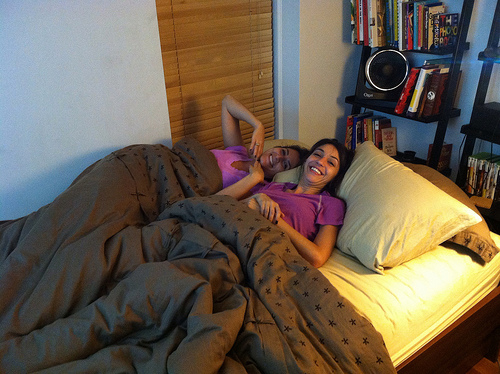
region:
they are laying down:
[255, 124, 365, 196]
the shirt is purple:
[301, 197, 326, 212]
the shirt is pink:
[220, 150, 230, 175]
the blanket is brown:
[161, 253, 197, 295]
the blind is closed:
[181, 66, 211, 98]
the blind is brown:
[236, 71, 261, 99]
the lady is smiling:
[308, 161, 325, 183]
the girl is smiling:
[263, 152, 278, 169]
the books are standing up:
[360, 8, 408, 36]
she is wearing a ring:
[253, 137, 262, 152]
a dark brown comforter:
[0, 139, 395, 372]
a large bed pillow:
[276, 141, 480, 271]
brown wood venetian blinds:
[155, 0, 275, 160]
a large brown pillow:
[403, 159, 498, 264]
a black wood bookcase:
[337, 0, 477, 169]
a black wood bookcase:
[448, 0, 499, 227]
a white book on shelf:
[407, 65, 443, 111]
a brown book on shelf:
[422, 69, 457, 117]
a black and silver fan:
[364, 48, 411, 98]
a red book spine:
[393, 69, 417, 116]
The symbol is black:
[269, 271, 286, 285]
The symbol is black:
[300, 285, 311, 300]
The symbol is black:
[309, 298, 324, 314]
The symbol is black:
[325, 313, 338, 333]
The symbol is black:
[336, 330, 351, 352]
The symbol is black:
[371, 350, 386, 366]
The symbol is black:
[356, 329, 373, 350]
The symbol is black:
[333, 294, 348, 318]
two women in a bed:
[183, 93, 368, 268]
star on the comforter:
[316, 303, 339, 335]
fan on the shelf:
[363, 47, 410, 97]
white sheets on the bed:
[387, 278, 430, 325]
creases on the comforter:
[110, 260, 166, 309]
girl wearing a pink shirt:
[210, 85, 301, 185]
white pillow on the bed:
[382, 177, 419, 237]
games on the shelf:
[460, 150, 498, 204]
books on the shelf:
[372, 20, 444, 47]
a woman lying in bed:
[246, 136, 344, 258]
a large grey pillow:
[313, 129, 473, 283]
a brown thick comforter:
[2, 144, 396, 372]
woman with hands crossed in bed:
[233, 132, 360, 266]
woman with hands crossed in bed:
[235, 125, 357, 261]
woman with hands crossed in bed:
[238, 129, 368, 266]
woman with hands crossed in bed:
[233, 128, 367, 268]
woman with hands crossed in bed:
[226, 135, 363, 276]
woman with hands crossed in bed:
[229, 126, 376, 271]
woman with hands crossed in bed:
[235, 128, 375, 268]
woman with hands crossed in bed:
[234, 128, 358, 268]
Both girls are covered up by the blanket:
[31, 83, 403, 372]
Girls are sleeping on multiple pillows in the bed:
[223, 122, 468, 269]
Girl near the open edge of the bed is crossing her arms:
[244, 136, 376, 298]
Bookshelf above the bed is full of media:
[307, 5, 498, 171]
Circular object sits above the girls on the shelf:
[346, 36, 430, 117]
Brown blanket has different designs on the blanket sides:
[35, 116, 420, 357]